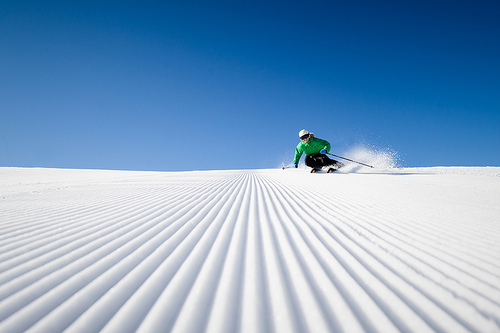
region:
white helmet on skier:
[284, 126, 309, 140]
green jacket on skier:
[294, 139, 331, 156]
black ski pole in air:
[330, 146, 384, 168]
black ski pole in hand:
[277, 159, 298, 177]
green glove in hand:
[288, 155, 306, 172]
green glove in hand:
[318, 149, 333, 159]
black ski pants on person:
[300, 149, 332, 170]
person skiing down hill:
[281, 112, 379, 182]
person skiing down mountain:
[272, 105, 384, 193]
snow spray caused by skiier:
[346, 135, 396, 181]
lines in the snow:
[217, 208, 329, 280]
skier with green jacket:
[283, 114, 375, 191]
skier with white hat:
[277, 116, 367, 174]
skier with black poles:
[277, 119, 363, 186]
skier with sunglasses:
[294, 118, 343, 173]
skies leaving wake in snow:
[274, 122, 391, 201]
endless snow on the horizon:
[45, 140, 159, 207]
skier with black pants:
[282, 116, 353, 180]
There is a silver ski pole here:
[341, 150, 356, 187]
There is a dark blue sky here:
[392, 20, 404, 67]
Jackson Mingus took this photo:
[188, 47, 277, 191]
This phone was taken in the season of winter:
[222, 45, 335, 292]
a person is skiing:
[273, 87, 366, 180]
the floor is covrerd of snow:
[123, 164, 275, 286]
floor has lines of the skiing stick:
[178, 233, 330, 295]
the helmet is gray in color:
[298, 116, 323, 141]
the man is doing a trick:
[275, 114, 367, 211]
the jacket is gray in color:
[297, 140, 344, 152]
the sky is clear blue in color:
[53, 35, 172, 114]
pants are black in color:
[305, 142, 347, 171]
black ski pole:
[326, 151, 374, 169]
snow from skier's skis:
[340, 142, 408, 173]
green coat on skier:
[294, 137, 329, 161]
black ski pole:
[279, 164, 294, 169]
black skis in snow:
[309, 165, 342, 174]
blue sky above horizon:
[1, 1, 497, 172]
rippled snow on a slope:
[1, 165, 498, 331]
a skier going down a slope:
[281, 128, 375, 172]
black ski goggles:
[299, 133, 308, 140]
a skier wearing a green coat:
[279, 128, 371, 176]